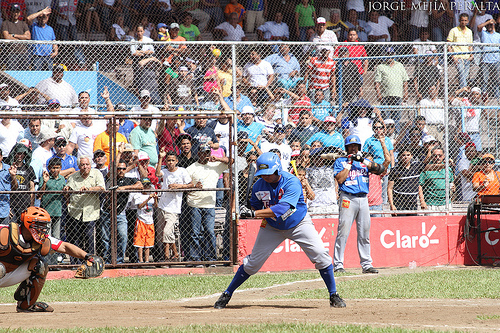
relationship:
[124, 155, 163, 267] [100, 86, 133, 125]
man holding his arm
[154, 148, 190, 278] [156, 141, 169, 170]
boy holding up h hand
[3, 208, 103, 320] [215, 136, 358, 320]
catcher behind batter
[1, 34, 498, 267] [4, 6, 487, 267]
fence in front of audience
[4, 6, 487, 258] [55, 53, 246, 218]
audience behind a fence